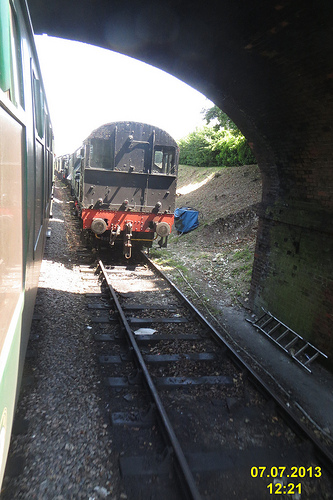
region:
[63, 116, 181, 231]
this is a train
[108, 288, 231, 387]
this is the railway line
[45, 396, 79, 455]
these are small rocks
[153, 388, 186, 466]
this is a metal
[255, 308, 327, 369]
this is a ladder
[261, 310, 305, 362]
the ladder is metallic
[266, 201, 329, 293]
this is the wall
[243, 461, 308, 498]
this is a writing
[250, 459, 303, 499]
the writing is in yellow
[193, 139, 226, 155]
this is a fence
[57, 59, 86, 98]
this is the sky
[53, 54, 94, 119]
the sky is bright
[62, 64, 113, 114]
the sky has some clouds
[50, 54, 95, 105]
the clouds are white in color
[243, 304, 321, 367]
this is a ladder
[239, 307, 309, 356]
the ladder is metallic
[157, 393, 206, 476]
this is a railway line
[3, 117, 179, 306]
these are two trains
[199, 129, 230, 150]
this is a bush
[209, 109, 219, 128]
the leaves are green in color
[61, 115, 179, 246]
train coming into tunnel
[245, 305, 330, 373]
silver ladder in tunnel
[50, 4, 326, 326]
wall and ceiling of tunnel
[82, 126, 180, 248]
black and red front of train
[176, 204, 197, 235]
blue tarp beside train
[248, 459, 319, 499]
yellow time stamp on photo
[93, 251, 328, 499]
tracks in front of train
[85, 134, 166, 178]
two windows on train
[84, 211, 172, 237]
red border on bottom of train car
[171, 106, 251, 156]
trees along embankment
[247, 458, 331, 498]
the date and time indicating the time of picture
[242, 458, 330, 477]
the date 07.07.2013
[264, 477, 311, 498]
the time 12:21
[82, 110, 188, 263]
front of a black and red train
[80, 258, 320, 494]
a steel railroad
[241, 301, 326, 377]
a steel ladder on the ground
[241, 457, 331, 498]
the date and time of picture in yellow font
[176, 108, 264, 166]
trees next to the railroad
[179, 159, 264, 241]
small uphill next to the railroad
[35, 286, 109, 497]
strip of gravel between two railroads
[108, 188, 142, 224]
part of a train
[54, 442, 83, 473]
part of a ground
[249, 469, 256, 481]
part of a number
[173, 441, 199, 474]
edge of a rail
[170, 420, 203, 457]
part of a rail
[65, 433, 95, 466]
part of a ground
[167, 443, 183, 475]
edge of a train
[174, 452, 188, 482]
edge of a rail